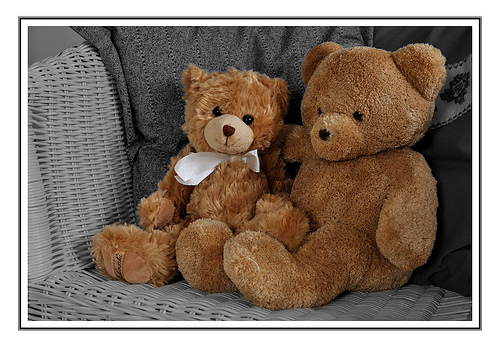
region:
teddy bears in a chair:
[87, 31, 468, 316]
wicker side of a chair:
[35, 54, 122, 278]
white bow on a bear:
[175, 141, 270, 188]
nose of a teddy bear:
[303, 113, 373, 160]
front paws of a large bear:
[174, 214, 299, 303]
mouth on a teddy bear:
[214, 134, 246, 150]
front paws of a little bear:
[93, 233, 162, 285]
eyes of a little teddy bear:
[204, 96, 264, 126]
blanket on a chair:
[88, 27, 176, 132]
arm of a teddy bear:
[373, 162, 448, 278]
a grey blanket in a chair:
[72, 27, 374, 211]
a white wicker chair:
[27, 41, 468, 321]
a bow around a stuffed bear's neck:
[169, 144, 263, 189]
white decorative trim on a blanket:
[424, 53, 470, 133]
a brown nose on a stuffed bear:
[221, 123, 236, 136]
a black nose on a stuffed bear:
[317, 128, 330, 140]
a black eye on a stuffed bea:
[209, 101, 225, 117]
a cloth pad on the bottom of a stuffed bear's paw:
[117, 247, 155, 287]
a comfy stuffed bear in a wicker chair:
[176, 38, 450, 307]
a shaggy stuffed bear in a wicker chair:
[90, 57, 296, 284]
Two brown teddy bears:
[87, 43, 442, 304]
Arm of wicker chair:
[36, 43, 158, 318]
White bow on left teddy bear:
[172, 135, 263, 185]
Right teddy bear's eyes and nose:
[303, 90, 377, 161]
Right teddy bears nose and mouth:
[205, 98, 259, 149]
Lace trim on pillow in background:
[443, 45, 474, 138]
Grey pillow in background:
[83, 28, 323, 90]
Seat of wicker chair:
[33, 261, 468, 318]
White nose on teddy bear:
[205, 112, 259, 158]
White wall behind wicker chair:
[28, 28, 84, 65]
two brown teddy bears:
[91, 42, 449, 319]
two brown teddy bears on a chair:
[27, 25, 476, 320]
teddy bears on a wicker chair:
[28, 27, 471, 322]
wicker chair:
[28, 43, 474, 322]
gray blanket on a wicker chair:
[70, 25, 372, 210]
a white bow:
[171, 145, 268, 185]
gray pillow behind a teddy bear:
[369, 25, 476, 300]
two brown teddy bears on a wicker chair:
[28, 25, 473, 318]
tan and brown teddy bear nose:
[200, 113, 257, 153]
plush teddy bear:
[176, 40, 452, 307]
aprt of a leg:
[246, 238, 290, 311]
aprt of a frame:
[398, 285, 426, 322]